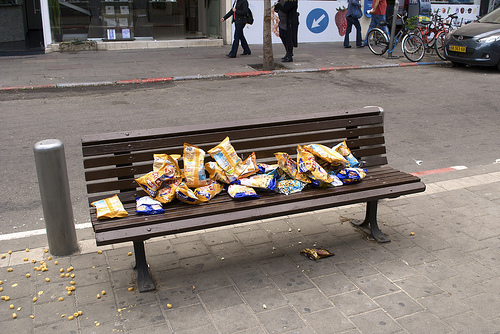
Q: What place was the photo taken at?
A: It was taken at the town.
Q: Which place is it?
A: It is a town.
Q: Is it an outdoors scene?
A: Yes, it is outdoors.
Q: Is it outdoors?
A: Yes, it is outdoors.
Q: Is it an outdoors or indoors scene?
A: It is outdoors.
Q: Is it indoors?
A: No, it is outdoors.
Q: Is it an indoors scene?
A: No, it is outdoors.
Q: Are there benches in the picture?
A: Yes, there is a bench.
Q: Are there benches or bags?
A: Yes, there is a bench.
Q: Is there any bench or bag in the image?
A: Yes, there is a bench.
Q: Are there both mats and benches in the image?
A: No, there is a bench but no mats.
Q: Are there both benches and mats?
A: No, there is a bench but no mats.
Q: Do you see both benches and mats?
A: No, there is a bench but no mats.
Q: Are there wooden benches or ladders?
A: Yes, there is a wood bench.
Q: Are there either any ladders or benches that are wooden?
A: Yes, the bench is wooden.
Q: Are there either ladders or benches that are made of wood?
A: Yes, the bench is made of wood.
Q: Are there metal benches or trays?
A: Yes, there is a metal bench.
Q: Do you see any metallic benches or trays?
A: Yes, there is a metal bench.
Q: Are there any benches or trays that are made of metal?
A: Yes, the bench is made of metal.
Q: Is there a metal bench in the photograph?
A: Yes, there is a metal bench.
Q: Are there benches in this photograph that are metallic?
A: Yes, there is a bench that is metallic.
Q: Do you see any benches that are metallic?
A: Yes, there is a bench that is metallic.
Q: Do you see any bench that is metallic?
A: Yes, there is a bench that is metallic.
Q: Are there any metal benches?
A: Yes, there is a bench that is made of metal.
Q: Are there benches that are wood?
A: Yes, there is a wood bench.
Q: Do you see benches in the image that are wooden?
A: Yes, there is a bench that is wooden.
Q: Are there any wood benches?
A: Yes, there is a bench that is made of wood.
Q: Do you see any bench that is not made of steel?
A: Yes, there is a bench that is made of wood.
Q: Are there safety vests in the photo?
A: No, there are no safety vests.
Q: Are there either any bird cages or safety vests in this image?
A: No, there are no safety vests or bird cages.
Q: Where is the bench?
A: The bench is on the sidewalk.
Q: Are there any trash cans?
A: No, there are no trash cans.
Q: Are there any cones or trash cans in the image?
A: No, there are no trash cans or cones.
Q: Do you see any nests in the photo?
A: No, there are no nests.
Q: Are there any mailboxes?
A: No, there are no mailboxes.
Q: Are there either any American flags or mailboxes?
A: No, there are no mailboxes or American flags.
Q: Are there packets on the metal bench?
A: Yes, there is a packet on the bench.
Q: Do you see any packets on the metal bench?
A: Yes, there is a packet on the bench.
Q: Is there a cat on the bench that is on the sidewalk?
A: No, there is a packet on the bench.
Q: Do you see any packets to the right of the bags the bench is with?
A: Yes, there is a packet to the right of the bags.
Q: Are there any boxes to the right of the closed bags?
A: No, there is a packet to the right of the bags.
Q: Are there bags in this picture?
A: Yes, there is a bag.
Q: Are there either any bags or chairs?
A: Yes, there is a bag.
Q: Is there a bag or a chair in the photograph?
A: Yes, there is a bag.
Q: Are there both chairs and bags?
A: No, there is a bag but no chairs.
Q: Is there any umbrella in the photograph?
A: No, there are no umbrellas.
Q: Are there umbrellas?
A: No, there are no umbrellas.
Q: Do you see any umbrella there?
A: No, there are no umbrellas.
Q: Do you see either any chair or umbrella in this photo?
A: No, there are no umbrellas or chairs.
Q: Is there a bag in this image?
A: Yes, there is a bag.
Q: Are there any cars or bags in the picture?
A: Yes, there is a bag.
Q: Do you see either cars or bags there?
A: Yes, there is a bag.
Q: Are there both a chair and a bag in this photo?
A: No, there is a bag but no chairs.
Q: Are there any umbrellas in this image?
A: No, there are no umbrellas.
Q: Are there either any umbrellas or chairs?
A: No, there are no umbrellas or chairs.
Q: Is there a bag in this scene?
A: Yes, there is a bag.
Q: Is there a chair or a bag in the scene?
A: Yes, there is a bag.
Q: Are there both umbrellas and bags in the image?
A: No, there is a bag but no umbrellas.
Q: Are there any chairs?
A: No, there are no chairs.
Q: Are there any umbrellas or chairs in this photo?
A: No, there are no chairs or umbrellas.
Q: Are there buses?
A: No, there are no buses.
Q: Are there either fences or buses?
A: No, there are no buses or fences.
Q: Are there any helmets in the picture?
A: No, there are no helmets.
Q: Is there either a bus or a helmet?
A: No, there are no helmets or buses.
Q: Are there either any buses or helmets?
A: No, there are no helmets or buses.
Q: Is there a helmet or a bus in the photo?
A: No, there are no helmets or buses.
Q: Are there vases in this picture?
A: No, there are no vases.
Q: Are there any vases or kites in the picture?
A: No, there are no vases or kites.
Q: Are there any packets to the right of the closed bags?
A: Yes, there is a packet to the right of the bags.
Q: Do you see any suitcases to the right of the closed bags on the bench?
A: No, there is a packet to the right of the bags.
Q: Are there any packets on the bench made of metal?
A: Yes, there is a packet on the bench.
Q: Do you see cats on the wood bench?
A: No, there is a packet on the bench.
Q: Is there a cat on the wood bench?
A: No, there is a packet on the bench.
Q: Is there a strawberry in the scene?
A: Yes, there is a strawberry.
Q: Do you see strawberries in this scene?
A: Yes, there is a strawberry.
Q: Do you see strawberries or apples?
A: Yes, there is a strawberry.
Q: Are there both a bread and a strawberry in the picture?
A: No, there is a strawberry but no breads.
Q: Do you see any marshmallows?
A: No, there are no marshmallows.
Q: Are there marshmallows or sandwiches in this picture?
A: No, there are no marshmallows or sandwiches.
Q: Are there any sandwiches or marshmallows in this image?
A: No, there are no marshmallows or sandwiches.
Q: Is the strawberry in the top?
A: Yes, the strawberry is in the top of the image.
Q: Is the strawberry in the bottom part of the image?
A: No, the strawberry is in the top of the image.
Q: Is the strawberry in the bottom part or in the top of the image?
A: The strawberry is in the top of the image.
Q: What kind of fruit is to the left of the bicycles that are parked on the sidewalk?
A: The fruit is a strawberry.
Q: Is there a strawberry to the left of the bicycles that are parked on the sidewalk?
A: Yes, there is a strawberry to the left of the bicycles.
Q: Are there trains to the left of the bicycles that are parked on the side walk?
A: No, there is a strawberry to the left of the bicycles.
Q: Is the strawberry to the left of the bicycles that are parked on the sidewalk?
A: Yes, the strawberry is to the left of the bicycles.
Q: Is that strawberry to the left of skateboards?
A: No, the strawberry is to the left of the bicycles.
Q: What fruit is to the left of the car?
A: The fruit is a strawberry.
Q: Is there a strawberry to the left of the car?
A: Yes, there is a strawberry to the left of the car.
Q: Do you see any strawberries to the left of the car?
A: Yes, there is a strawberry to the left of the car.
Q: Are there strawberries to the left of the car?
A: Yes, there is a strawberry to the left of the car.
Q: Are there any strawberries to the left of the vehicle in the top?
A: Yes, there is a strawberry to the left of the car.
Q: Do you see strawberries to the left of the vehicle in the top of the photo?
A: Yes, there is a strawberry to the left of the car.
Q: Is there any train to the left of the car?
A: No, there is a strawberry to the left of the car.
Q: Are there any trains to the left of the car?
A: No, there is a strawberry to the left of the car.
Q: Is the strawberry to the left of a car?
A: Yes, the strawberry is to the left of a car.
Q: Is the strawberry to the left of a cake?
A: No, the strawberry is to the left of a car.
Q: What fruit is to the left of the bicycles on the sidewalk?
A: The fruit is a strawberry.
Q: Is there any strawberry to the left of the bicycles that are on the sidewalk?
A: Yes, there is a strawberry to the left of the bicycles.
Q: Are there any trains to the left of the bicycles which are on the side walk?
A: No, there is a strawberry to the left of the bicycles.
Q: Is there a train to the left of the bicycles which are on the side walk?
A: No, there is a strawberry to the left of the bicycles.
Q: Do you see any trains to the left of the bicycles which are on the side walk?
A: No, there is a strawberry to the left of the bicycles.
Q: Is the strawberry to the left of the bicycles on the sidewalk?
A: Yes, the strawberry is to the left of the bicycles.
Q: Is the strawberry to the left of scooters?
A: No, the strawberry is to the left of the bicycles.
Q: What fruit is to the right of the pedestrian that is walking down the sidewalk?
A: The fruit is a strawberry.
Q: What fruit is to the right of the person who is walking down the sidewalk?
A: The fruit is a strawberry.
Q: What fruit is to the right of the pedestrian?
A: The fruit is a strawberry.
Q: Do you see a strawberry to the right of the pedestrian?
A: Yes, there is a strawberry to the right of the pedestrian.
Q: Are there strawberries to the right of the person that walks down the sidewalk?
A: Yes, there is a strawberry to the right of the pedestrian.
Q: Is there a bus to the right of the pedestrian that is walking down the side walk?
A: No, there is a strawberry to the right of the pedestrian.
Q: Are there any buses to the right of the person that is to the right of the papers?
A: No, there is a strawberry to the right of the pedestrian.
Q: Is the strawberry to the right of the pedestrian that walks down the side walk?
A: Yes, the strawberry is to the right of the pedestrian.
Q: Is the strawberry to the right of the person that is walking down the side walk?
A: Yes, the strawberry is to the right of the pedestrian.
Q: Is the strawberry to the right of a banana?
A: No, the strawberry is to the right of the pedestrian.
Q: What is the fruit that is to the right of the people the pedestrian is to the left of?
A: The fruit is a strawberry.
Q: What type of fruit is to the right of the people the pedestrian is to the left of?
A: The fruit is a strawberry.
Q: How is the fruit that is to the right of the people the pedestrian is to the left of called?
A: The fruit is a strawberry.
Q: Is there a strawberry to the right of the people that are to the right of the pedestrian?
A: Yes, there is a strawberry to the right of the people.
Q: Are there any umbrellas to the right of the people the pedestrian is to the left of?
A: No, there is a strawberry to the right of the people.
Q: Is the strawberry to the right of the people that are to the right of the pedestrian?
A: Yes, the strawberry is to the right of the people.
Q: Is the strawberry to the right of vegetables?
A: No, the strawberry is to the right of the people.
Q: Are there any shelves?
A: No, there are no shelves.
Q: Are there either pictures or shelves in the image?
A: No, there are no shelves or pictures.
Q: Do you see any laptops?
A: No, there are no laptops.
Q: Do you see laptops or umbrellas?
A: No, there are no laptops or umbrellas.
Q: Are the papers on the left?
A: Yes, the papers are on the left of the image.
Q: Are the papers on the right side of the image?
A: No, the papers are on the left of the image.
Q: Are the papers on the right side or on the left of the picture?
A: The papers are on the left of the image.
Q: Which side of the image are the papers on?
A: The papers are on the left of the image.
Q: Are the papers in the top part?
A: Yes, the papers are in the top of the image.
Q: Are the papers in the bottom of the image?
A: No, the papers are in the top of the image.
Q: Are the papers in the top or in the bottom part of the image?
A: The papers are in the top of the image.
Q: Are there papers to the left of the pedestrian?
A: Yes, there are papers to the left of the pedestrian.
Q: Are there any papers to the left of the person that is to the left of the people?
A: Yes, there are papers to the left of the pedestrian.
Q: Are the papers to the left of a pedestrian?
A: Yes, the papers are to the left of a pedestrian.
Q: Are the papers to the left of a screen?
A: No, the papers are to the left of a pedestrian.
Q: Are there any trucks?
A: No, there are no trucks.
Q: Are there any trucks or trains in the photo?
A: No, there are no trucks or trains.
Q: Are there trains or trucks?
A: No, there are no trucks or trains.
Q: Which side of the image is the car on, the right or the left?
A: The car is on the right of the image.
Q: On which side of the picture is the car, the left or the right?
A: The car is on the right of the image.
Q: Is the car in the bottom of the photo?
A: No, the car is in the top of the image.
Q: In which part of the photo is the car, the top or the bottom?
A: The car is in the top of the image.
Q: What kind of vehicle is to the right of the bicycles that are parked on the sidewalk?
A: The vehicle is a car.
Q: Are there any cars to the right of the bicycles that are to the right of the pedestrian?
A: Yes, there is a car to the right of the bicycles.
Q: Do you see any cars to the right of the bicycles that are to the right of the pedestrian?
A: Yes, there is a car to the right of the bicycles.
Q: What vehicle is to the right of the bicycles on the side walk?
A: The vehicle is a car.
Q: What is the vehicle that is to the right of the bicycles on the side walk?
A: The vehicle is a car.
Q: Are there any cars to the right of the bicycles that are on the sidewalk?
A: Yes, there is a car to the right of the bicycles.